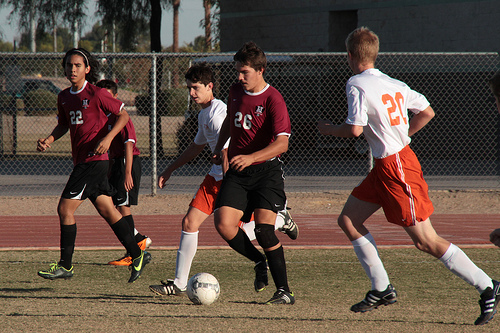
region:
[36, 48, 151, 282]
Number 22 soccer player.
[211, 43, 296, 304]
Number 26 soccer player.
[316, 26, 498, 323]
Number 20 soccer player.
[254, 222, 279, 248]
Black knee brace on a player.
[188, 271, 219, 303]
Gray and white soccer ball.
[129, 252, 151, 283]
Black shoe with green Nike check.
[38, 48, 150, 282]
Soccer player wearing a head band.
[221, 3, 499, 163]
Gray brick building behind the fence.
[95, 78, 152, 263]
Soccer player wearing orange shoes.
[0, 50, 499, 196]
Chain link fence around the area.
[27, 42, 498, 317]
group playing ball on field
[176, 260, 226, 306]
ball on the field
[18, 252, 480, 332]
field where game is played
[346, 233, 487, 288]
socks on the player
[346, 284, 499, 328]
shoes on the player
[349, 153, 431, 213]
shorts on the player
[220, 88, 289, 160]
shirt on the player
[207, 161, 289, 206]
shorts on the player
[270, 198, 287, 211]
logo on the shorts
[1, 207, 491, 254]
track behind the field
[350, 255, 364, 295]
part of a ground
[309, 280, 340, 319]
part of a shade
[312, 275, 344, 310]
part of a ground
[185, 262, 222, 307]
the white soccer ball on the field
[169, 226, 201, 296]
the high white sock on the leg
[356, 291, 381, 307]
the three white lines on the black shoe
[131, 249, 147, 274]
the green swoosh on the shoe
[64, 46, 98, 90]
the white band on the boys head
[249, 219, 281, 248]
the brace on the boys knee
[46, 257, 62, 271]
the green laces on the shoe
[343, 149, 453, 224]
the orange pair of shorts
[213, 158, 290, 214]
the black pair of shorts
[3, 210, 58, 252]
the red track behind the soccer players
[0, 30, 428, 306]
They are playing soccer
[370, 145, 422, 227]
his shorts are orange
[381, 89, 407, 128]
his number is orange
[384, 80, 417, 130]
his number is 20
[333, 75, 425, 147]
his shirt is white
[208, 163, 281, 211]
his shorts are black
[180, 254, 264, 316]
The ball is on the ground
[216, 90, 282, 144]
His shirt is red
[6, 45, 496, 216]
The fence is metal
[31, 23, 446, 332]
Four kids playing soccer